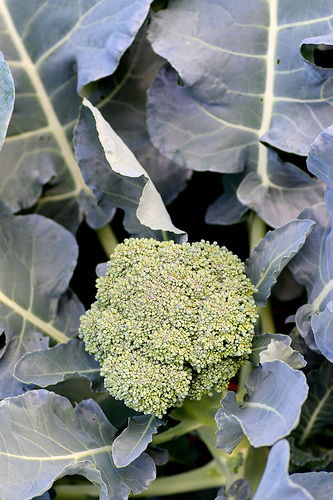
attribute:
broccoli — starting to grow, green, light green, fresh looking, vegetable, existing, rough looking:
[0, 3, 331, 499]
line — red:
[226, 379, 242, 394]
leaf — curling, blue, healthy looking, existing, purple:
[67, 96, 188, 244]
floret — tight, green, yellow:
[71, 233, 255, 428]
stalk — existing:
[153, 420, 198, 449]